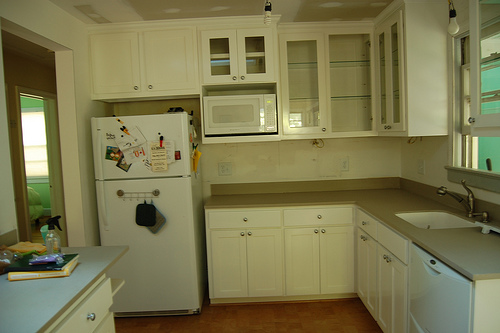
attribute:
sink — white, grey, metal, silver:
[391, 180, 483, 242]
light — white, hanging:
[443, 6, 462, 38]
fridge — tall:
[85, 110, 203, 316]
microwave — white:
[196, 92, 279, 140]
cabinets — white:
[89, 26, 200, 102]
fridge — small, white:
[130, 90, 200, 290]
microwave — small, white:
[213, 91, 262, 129]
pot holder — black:
[138, 210, 148, 222]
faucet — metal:
[436, 183, 449, 202]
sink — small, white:
[405, 211, 468, 224]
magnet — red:
[158, 140, 163, 147]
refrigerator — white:
[136, 174, 199, 317]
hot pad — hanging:
[134, 206, 152, 223]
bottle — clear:
[46, 232, 60, 249]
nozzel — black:
[53, 210, 59, 220]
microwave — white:
[210, 97, 272, 130]